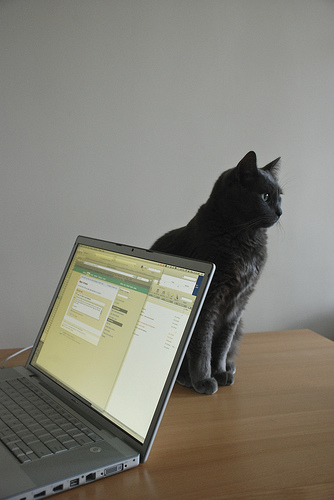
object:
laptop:
[0, 222, 216, 491]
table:
[2, 327, 332, 499]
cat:
[145, 149, 283, 397]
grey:
[141, 151, 284, 396]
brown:
[2, 327, 329, 495]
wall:
[0, 8, 333, 351]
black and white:
[262, 192, 270, 201]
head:
[210, 150, 291, 227]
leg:
[183, 307, 219, 398]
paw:
[192, 377, 221, 395]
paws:
[216, 368, 235, 387]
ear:
[237, 147, 259, 180]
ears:
[263, 156, 283, 180]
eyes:
[279, 192, 283, 197]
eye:
[261, 192, 269, 202]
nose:
[275, 208, 283, 218]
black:
[143, 151, 283, 396]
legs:
[213, 316, 235, 387]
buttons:
[0, 375, 104, 466]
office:
[6, 2, 333, 497]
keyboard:
[1, 374, 105, 469]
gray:
[4, 374, 105, 473]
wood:
[4, 326, 332, 497]